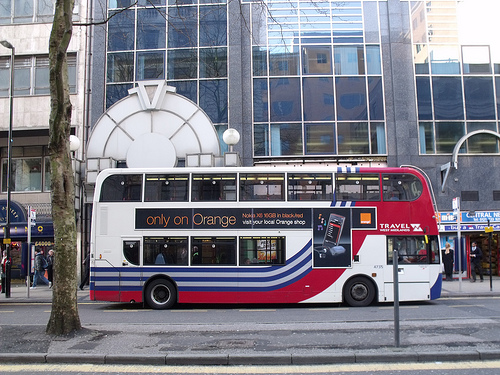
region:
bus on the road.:
[88, 152, 443, 309]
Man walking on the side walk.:
[466, 231, 486, 283]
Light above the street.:
[0, 34, 18, 55]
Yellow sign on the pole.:
[480, 220, 499, 235]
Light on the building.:
[220, 120, 240, 153]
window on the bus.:
[382, 230, 438, 268]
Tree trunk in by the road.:
[28, 0, 95, 335]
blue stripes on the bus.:
[90, 238, 312, 293]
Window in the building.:
[2, 153, 46, 198]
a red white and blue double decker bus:
[89, 162, 446, 308]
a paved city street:
[0, 297, 497, 323]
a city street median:
[1, 320, 497, 363]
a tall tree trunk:
[47, 2, 80, 332]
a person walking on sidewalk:
[30, 246, 52, 289]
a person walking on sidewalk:
[470, 241, 485, 281]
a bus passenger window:
[238, 235, 282, 266]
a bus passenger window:
[190, 235, 235, 265]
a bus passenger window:
[142, 237, 187, 266]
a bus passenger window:
[100, 174, 142, 201]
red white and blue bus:
[92, 166, 442, 309]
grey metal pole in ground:
[391, 250, 401, 347]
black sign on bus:
[311, 207, 355, 270]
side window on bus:
[386, 235, 439, 266]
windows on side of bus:
[142, 234, 289, 269]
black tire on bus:
[143, 274, 176, 309]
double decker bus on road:
[91, 164, 446, 309]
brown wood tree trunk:
[45, 2, 87, 335]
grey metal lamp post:
[1, 38, 18, 292]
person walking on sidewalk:
[28, 247, 51, 289]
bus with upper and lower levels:
[91, 146, 443, 314]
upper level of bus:
[103, 172, 413, 202]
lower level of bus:
[93, 235, 383, 284]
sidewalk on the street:
[168, 324, 494, 347]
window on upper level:
[146, 173, 191, 204]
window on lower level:
[192, 238, 239, 269]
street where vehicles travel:
[123, 307, 357, 324]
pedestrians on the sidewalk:
[1, 244, 58, 284]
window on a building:
[257, 22, 373, 151]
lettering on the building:
[453, 209, 496, 229]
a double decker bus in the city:
[67, 133, 473, 330]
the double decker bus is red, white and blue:
[88, 151, 463, 326]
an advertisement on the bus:
[125, 192, 323, 242]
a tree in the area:
[40, 165, 94, 339]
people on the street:
[8, 227, 65, 284]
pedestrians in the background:
[438, 227, 488, 286]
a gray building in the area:
[95, 8, 489, 163]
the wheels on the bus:
[123, 264, 410, 323]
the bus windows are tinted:
[104, 167, 434, 218]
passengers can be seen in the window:
[115, 230, 310, 266]